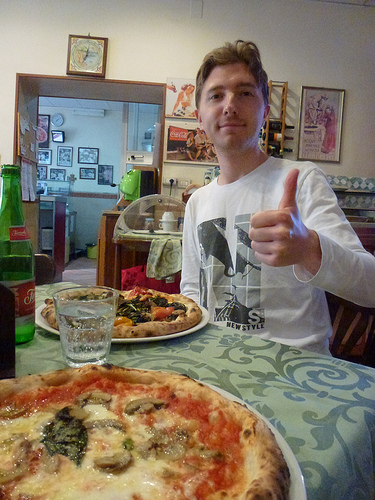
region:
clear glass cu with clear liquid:
[52, 285, 118, 362]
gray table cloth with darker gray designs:
[13, 321, 374, 496]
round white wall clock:
[51, 112, 64, 126]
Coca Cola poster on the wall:
[166, 124, 217, 160]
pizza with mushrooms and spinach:
[0, 363, 289, 496]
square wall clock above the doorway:
[66, 33, 108, 75]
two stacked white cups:
[158, 210, 176, 229]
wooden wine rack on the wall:
[261, 79, 285, 156]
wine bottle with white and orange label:
[261, 132, 292, 141]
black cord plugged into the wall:
[167, 179, 173, 204]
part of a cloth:
[309, 412, 326, 445]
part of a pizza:
[181, 451, 209, 494]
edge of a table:
[319, 429, 342, 465]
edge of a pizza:
[257, 406, 298, 439]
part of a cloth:
[313, 397, 333, 436]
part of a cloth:
[317, 370, 340, 403]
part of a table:
[300, 392, 321, 425]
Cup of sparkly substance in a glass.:
[49, 286, 119, 361]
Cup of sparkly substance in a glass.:
[45, 112, 69, 144]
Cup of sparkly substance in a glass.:
[0, 155, 38, 352]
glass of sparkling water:
[52, 282, 118, 367]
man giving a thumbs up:
[178, 37, 374, 350]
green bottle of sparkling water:
[0, 158, 38, 343]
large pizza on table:
[1, 356, 309, 499]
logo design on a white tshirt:
[191, 210, 271, 335]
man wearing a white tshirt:
[180, 148, 373, 348]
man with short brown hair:
[189, 35, 272, 157]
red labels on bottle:
[8, 224, 40, 322]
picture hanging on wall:
[62, 27, 110, 80]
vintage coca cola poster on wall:
[162, 116, 223, 164]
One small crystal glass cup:
[51, 291, 132, 366]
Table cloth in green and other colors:
[281, 355, 359, 460]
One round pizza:
[4, 366, 334, 496]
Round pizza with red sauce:
[3, 365, 312, 494]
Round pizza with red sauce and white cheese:
[6, 358, 317, 495]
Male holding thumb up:
[174, 30, 370, 405]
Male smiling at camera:
[183, 39, 372, 375]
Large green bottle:
[2, 165, 42, 364]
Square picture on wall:
[61, 26, 117, 83]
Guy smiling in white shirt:
[175, 45, 372, 374]